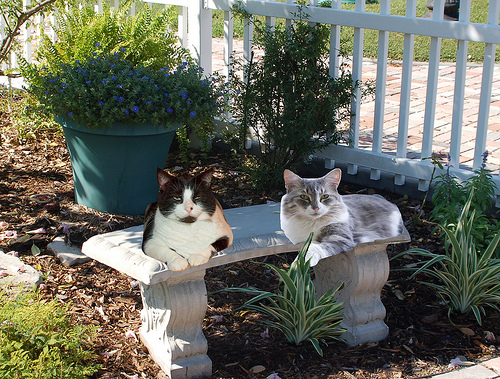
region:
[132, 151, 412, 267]
the cat's have been photoshopped into the picture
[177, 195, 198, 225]
the cat's nose is pink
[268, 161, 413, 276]
the cat is grey and white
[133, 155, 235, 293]
the cat is yellow black and white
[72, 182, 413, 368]
this is a stone bench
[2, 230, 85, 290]
the stones are grey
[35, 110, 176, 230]
the flower pot is plastic and green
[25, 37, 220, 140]
the flowers are small and blue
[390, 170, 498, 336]
this is monkey grass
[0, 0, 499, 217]
the fence is white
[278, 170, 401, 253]
this is a cat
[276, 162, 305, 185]
this is the ear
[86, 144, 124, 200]
this is a container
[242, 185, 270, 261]
this is a bench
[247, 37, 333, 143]
this is a tree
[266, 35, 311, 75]
the leaves are green in color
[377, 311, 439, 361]
this is the soil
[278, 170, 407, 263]
a white and gray cat on a stone bench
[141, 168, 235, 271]
a black and white cat on a stone bench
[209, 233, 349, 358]
a green plant coming out of the soil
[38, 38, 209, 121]
blue flowers in a green plant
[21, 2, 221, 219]
a green plant in a green pot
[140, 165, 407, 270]
two cats laying on a stone bench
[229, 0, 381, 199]
a green plant next to a white fence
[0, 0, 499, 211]
a white wooden fence in a garden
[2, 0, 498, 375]
green plants in a garden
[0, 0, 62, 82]
a wood branch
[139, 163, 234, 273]
A black and white cat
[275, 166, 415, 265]
A cat sitting on the bench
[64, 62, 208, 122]
Blue flowers in pot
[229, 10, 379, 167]
Green tree on the ground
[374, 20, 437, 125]
Part of the fence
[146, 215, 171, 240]
Black and white fur on cat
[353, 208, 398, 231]
Gray and white fur on cat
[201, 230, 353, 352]
A planet under the bench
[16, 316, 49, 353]
Part of green bush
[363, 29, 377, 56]
Part of the green grass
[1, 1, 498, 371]
two photo realistic cats sitting on a stone bench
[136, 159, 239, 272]
photo cut out of a black and white cat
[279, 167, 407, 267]
photo cut out of a grey and white cat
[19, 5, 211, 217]
large blue flowering plant inside a green pot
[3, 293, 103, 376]
small light green shrub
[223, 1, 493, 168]
dark green plant in front of white picket fence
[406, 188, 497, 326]
light green and white foliage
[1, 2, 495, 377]
two cats sitting in a garden on a bench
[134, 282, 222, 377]
carved leg of a stone bench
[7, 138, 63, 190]
brown mulch and dirt